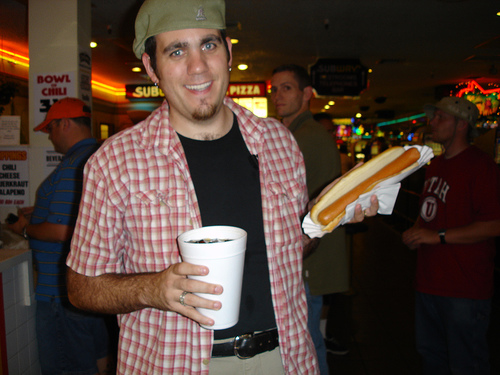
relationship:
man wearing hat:
[63, 5, 435, 360] [121, 8, 238, 46]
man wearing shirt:
[63, 5, 435, 360] [70, 107, 327, 368]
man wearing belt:
[63, 5, 435, 360] [204, 329, 283, 359]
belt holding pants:
[204, 329, 283, 359] [199, 334, 319, 369]